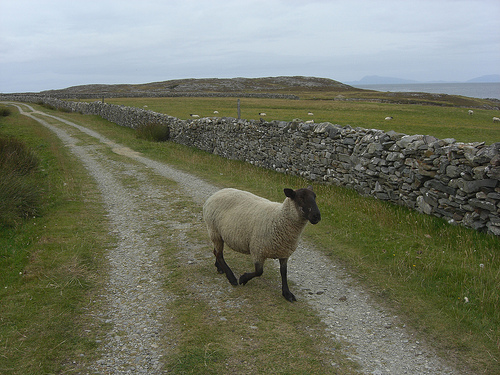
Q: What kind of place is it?
A: It is a road.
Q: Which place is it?
A: It is a road.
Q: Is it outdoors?
A: Yes, it is outdoors.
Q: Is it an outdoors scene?
A: Yes, it is outdoors.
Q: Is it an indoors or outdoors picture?
A: It is outdoors.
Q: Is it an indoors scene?
A: No, it is outdoors.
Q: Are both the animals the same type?
A: Yes, all the animals are sheep.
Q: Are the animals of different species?
A: No, all the animals are sheep.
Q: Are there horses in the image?
A: No, there are no horses.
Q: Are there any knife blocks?
A: No, there are no knife blocks.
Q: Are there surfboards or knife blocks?
A: No, there are no knife blocks or surfboards.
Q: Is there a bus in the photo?
A: No, there are no buses.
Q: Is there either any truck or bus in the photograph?
A: No, there are no buses or trucks.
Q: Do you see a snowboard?
A: No, there are no snowboards.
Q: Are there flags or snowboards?
A: No, there are no snowboards or flags.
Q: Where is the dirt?
A: The dirt is on the road.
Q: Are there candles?
A: No, there are no candles.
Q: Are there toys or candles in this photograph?
A: No, there are no candles or toys.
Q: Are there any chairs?
A: No, there are no chairs.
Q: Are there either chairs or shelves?
A: No, there are no chairs or shelves.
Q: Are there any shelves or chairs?
A: No, there are no chairs or shelves.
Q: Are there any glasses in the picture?
A: No, there are no glasses.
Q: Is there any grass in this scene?
A: Yes, there is grass.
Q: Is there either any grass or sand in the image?
A: Yes, there is grass.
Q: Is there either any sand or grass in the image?
A: Yes, there is grass.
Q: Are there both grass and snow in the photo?
A: No, there is grass but no snow.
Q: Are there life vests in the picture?
A: No, there are no life vests.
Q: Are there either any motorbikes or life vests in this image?
A: No, there are no life vests or motorbikes.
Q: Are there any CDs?
A: No, there are no cds.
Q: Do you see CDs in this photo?
A: No, there are no cds.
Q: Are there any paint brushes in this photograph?
A: No, there are no paint brushes.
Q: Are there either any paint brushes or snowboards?
A: No, there are no paint brushes or snowboards.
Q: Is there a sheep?
A: Yes, there is a sheep.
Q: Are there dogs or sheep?
A: Yes, there is a sheep.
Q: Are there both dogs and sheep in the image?
A: No, there is a sheep but no dogs.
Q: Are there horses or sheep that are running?
A: Yes, the sheep is running.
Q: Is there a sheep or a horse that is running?
A: Yes, the sheep is running.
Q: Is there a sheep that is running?
A: Yes, there is a sheep that is running.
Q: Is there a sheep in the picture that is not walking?
A: Yes, there is a sheep that is running.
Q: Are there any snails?
A: No, there are no snails.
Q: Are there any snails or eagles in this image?
A: No, there are no snails or eagles.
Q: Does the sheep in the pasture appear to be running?
A: Yes, the sheep is running.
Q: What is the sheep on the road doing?
A: The sheep is running.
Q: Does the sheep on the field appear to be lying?
A: No, the sheep is running.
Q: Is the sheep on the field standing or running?
A: The sheep is running.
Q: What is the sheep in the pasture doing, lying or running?
A: The sheep is running.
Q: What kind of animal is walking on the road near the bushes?
A: The animal is a sheep.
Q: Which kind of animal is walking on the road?
A: The animal is a sheep.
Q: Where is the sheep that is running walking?
A: The sheep is walking on the road.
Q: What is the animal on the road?
A: The animal is a sheep.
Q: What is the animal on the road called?
A: The animal is a sheep.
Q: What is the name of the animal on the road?
A: The animal is a sheep.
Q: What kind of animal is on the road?
A: The animal is a sheep.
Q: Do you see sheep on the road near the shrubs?
A: Yes, there is a sheep on the road.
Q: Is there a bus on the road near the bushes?
A: No, there is a sheep on the road.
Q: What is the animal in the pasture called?
A: The animal is a sheep.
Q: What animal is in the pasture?
A: The animal is a sheep.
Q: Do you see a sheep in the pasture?
A: Yes, there is a sheep in the pasture.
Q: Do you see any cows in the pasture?
A: No, there is a sheep in the pasture.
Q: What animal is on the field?
A: The animal is a sheep.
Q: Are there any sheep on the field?
A: Yes, there is a sheep on the field.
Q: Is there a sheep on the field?
A: Yes, there is a sheep on the field.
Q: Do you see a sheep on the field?
A: Yes, there is a sheep on the field.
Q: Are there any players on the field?
A: No, there is a sheep on the field.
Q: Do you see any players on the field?
A: No, there is a sheep on the field.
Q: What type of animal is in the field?
A: The animal is a sheep.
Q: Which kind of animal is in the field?
A: The animal is a sheep.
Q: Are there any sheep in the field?
A: Yes, there is a sheep in the field.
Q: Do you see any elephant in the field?
A: No, there is a sheep in the field.